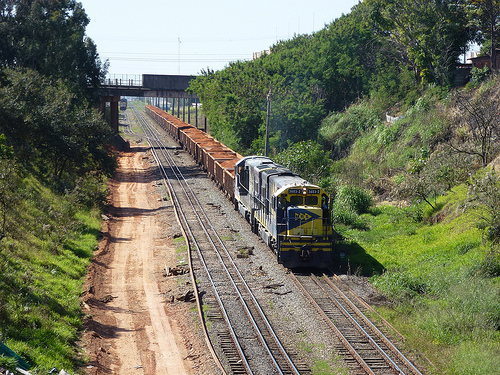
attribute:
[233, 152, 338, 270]
train — blue, driving, yellow, long, large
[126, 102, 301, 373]
track — metal, long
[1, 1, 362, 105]
sky — bright, sunny, clear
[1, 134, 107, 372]
grass — green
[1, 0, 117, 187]
trees — large, green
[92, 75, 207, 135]
bridge — big, large